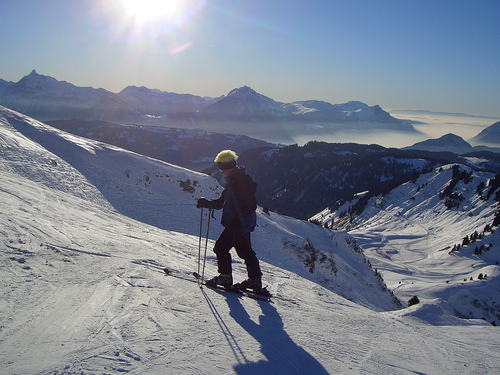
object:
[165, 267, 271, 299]
snowboard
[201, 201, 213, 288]
ski pole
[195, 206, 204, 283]
ski pole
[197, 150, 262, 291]
man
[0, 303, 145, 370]
snow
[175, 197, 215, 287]
skipoles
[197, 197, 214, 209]
black color gloves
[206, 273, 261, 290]
pair of shoes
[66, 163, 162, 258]
white color snow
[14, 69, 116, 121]
big mountain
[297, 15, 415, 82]
blue color sky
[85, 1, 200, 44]
sun lights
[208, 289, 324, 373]
shadow of the person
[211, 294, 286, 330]
part of a shade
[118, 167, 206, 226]
shade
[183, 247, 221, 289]
part of a hokker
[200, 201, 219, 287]
snow with ski stick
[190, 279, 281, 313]
in the snow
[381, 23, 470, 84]
sky is blue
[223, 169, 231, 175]
man is light skinned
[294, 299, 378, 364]
snow is white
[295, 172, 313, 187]
this is a tree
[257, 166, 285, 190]
leaves are green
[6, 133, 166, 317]
snowy slope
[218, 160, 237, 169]
black knit cap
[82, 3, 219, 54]
sun shining above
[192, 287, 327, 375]
shadow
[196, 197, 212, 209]
hands gripping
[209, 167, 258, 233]
blue jacket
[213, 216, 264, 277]
black pants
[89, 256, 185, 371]
ski tracks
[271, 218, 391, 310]
black rocks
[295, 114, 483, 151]
white mountain mist